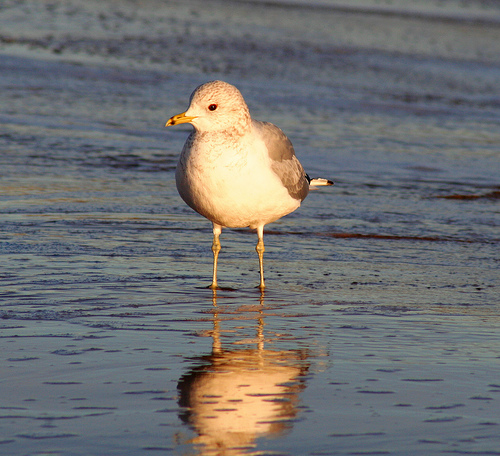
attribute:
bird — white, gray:
[162, 80, 331, 297]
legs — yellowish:
[207, 223, 267, 294]